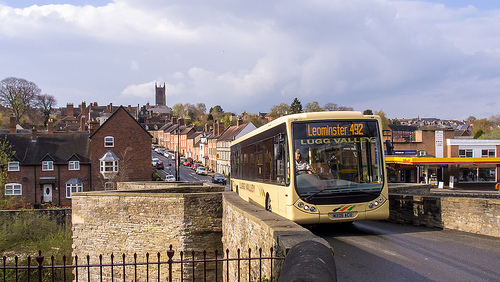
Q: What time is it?
A: Afternoon.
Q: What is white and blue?
A: The bus.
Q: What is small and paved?
A: The bridge.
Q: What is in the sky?
A: Clouds.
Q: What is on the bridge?
A: A bus.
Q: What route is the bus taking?
A: Leominster 492.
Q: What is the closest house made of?
A: Brick.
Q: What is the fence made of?
A: Iron.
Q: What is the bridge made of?
A: Bricks.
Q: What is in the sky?
A: Clouds.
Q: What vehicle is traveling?
A: Bus.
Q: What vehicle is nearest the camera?
A: Bus.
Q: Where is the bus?
A: Bridge.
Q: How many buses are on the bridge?
A: One.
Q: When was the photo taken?
A: Daytime.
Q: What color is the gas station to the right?
A: Yellow.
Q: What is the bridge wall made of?
A: Stones.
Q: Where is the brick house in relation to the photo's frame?
A: Left.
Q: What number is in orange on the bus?
A: 492.